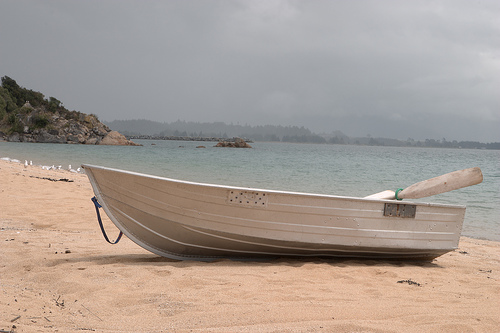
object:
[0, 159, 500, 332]
beach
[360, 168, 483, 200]
oar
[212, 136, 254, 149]
outcropping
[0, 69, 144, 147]
land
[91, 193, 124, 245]
rope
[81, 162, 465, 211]
waters edge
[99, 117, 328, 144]
tree line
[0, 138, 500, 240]
ocean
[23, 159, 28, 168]
seagull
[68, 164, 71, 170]
seagull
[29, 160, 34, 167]
seagull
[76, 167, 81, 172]
seagull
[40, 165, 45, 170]
seagulls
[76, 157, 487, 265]
aluminum canoe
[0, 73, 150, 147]
rocks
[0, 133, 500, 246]
water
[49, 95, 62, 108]
trees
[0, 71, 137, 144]
hillside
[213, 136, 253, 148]
small island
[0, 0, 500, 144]
sky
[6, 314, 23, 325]
sticks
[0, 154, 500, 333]
sand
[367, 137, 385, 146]
trees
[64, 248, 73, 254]
stuff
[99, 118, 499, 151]
island